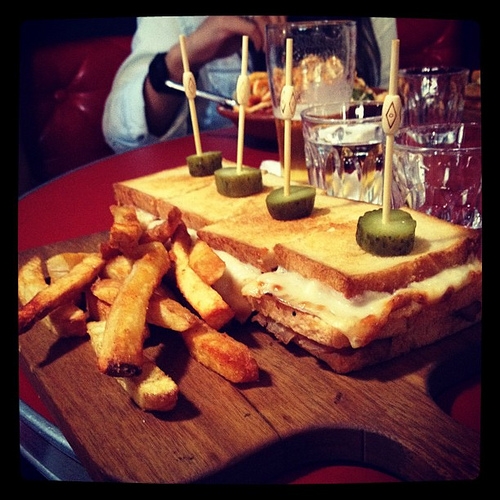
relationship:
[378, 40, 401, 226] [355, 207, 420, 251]
skewer through pickle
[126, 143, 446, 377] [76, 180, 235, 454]
cheese on sandwich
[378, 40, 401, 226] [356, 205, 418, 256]
skewer in pickle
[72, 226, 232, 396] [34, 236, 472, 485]
fries lying board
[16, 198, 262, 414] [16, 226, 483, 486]
fries lying board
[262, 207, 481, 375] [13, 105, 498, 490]
sandwich sitting table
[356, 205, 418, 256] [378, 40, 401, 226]
pickle held down skewer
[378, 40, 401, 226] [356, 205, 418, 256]
skewer securing pickle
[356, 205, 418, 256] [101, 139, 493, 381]
pickle on sandwich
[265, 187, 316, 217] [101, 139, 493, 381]
pickle on sandwich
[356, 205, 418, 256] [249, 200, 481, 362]
pickle on sandwich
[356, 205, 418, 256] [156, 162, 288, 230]
pickle on bread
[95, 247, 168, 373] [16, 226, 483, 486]
fries on board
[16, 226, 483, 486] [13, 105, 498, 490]
board on table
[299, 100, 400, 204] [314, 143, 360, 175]
cups with water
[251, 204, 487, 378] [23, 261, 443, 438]
sandwich on board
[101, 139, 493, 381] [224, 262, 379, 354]
sandwich with cheese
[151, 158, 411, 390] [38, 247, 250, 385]
sandwich and fries